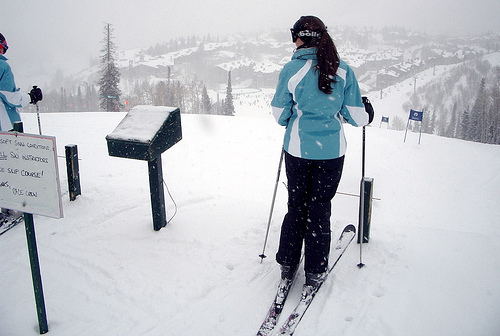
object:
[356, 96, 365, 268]
ski pole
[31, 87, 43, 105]
hand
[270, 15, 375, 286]
girl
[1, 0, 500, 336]
snow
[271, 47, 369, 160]
jacket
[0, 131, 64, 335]
sign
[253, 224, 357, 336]
skis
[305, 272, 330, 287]
ski boot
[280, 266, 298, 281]
ski boot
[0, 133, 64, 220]
warning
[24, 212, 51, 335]
pole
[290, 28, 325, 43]
goggles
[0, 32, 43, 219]
person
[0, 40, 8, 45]
goggles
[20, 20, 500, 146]
tree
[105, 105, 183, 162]
box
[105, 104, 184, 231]
post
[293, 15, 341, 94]
hair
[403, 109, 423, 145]
ski marker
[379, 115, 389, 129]
ski marker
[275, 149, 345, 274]
pants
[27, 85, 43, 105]
glove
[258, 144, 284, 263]
ski pole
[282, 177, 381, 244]
gate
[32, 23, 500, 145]
mountain